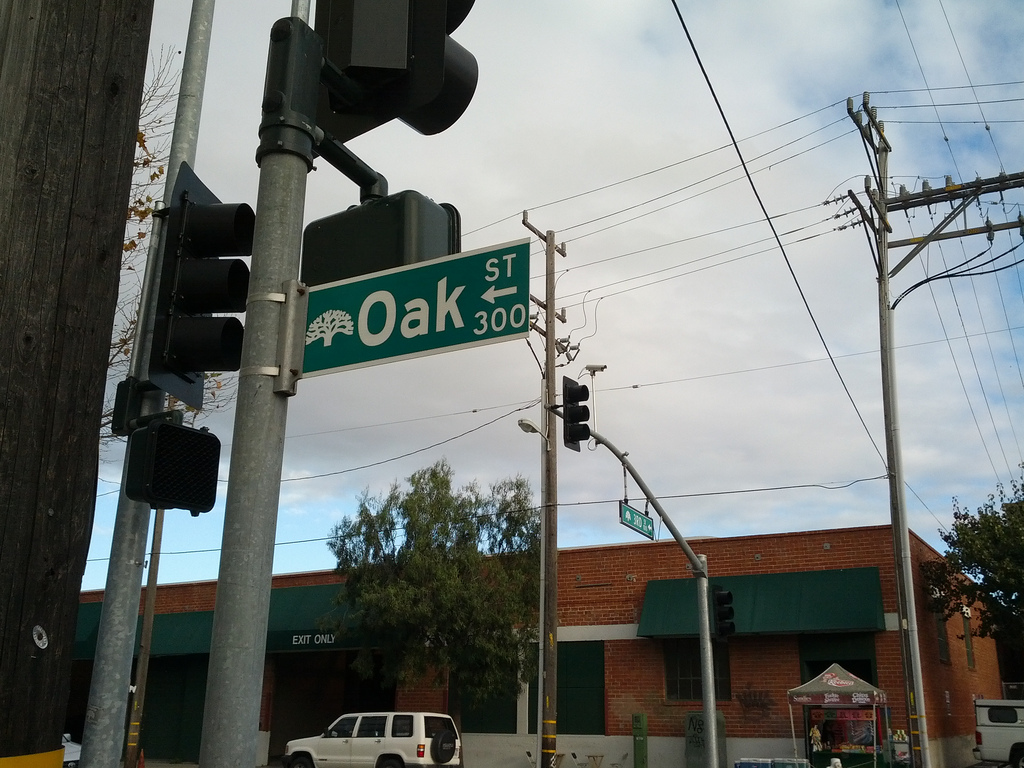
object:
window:
[665, 636, 733, 701]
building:
[80, 525, 1024, 768]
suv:
[285, 712, 461, 768]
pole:
[874, 113, 932, 768]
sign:
[301, 237, 533, 379]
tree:
[318, 455, 542, 735]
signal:
[147, 161, 256, 411]